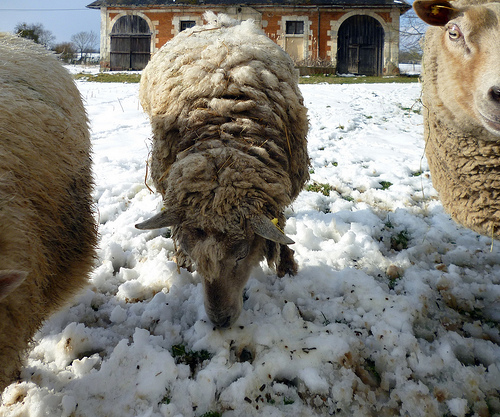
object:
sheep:
[131, 6, 315, 331]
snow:
[2, 84, 499, 417]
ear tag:
[270, 216, 286, 236]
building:
[83, 0, 412, 84]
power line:
[1, 7, 100, 12]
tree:
[69, 29, 100, 65]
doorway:
[330, 6, 400, 83]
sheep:
[408, 0, 500, 248]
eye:
[443, 23, 467, 42]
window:
[295, 21, 306, 34]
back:
[142, 17, 318, 159]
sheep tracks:
[375, 214, 424, 261]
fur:
[158, 72, 306, 189]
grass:
[65, 66, 424, 83]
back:
[0, 0, 497, 83]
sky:
[0, 0, 498, 55]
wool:
[201, 96, 254, 114]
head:
[134, 206, 299, 330]